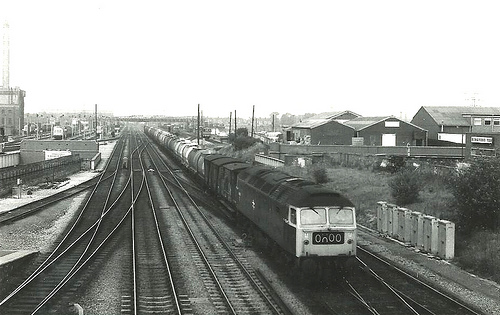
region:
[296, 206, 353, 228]
the windows on the engine of the train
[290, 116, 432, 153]
storage buildings in the distance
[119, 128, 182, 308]
the train track is made in metal and wood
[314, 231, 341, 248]
lettering on the front of the train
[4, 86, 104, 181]
a brick building in the distance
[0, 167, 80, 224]
the platform off the track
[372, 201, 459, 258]
electrical boxes on the side of the track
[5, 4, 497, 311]
the picture is in black and white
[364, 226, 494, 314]
gravel on the side of the tracks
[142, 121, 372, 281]
the train has 7 cars attached to it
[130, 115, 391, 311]
A train is on the tracks.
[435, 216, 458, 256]
The object is rectangular in shape.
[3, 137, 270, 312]
An empty part of the railroad tracks.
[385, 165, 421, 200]
A small bush near the train.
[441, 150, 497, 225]
A larger bush near the small bush.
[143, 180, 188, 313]
A rail on the tracks.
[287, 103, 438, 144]
A buiding near the train.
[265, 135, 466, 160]
A fence next to the building.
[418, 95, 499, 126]
The roof of a building.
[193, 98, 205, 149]
A pole in the distance.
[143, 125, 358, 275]
A train on tracks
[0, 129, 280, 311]
some railroad tracks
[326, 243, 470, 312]
some railroad tracks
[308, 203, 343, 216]
windshield wipers on the train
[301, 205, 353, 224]
the windshield of the train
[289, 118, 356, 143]
A large building behind a fence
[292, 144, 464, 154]
A long fence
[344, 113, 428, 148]
A large building behind a fence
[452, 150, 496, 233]
A large bush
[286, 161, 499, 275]
A grassy landscape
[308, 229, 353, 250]
0s on the train.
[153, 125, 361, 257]
Train on the tracks.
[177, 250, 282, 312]
Gravel around the tracks.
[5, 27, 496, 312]
Taken in black and white.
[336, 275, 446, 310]
The tracks are grey.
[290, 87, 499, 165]
Buildings in the background.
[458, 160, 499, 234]
Tree next to the tracks.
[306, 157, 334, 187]
Small bush on the ground.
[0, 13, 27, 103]
Tower on the side.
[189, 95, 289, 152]
Poles in the background.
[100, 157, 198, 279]
Several train tracks on ground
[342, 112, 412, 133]
Roof of a house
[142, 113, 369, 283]
Very long train on tracks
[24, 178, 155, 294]
Train tracks that are splittong off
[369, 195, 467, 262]
White boxed next to tracks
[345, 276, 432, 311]
Train tracks splitting off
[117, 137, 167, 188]
Train tracks splitting off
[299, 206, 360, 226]
Front windows to the train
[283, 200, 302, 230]
Side window to the train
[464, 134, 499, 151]
White sign on brick building